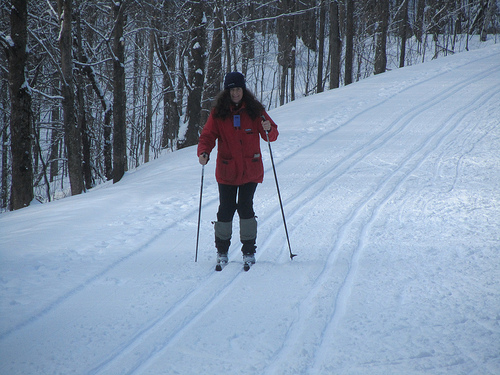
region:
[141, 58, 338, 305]
the woman is skiing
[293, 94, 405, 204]
ski tracks in the snow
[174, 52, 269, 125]
woman wearing a hat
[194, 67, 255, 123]
the hat is black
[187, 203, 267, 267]
the woman is wearing leg warmers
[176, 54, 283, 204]
the woman is wearing a red coat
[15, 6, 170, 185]
the trees have snow on them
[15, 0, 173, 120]
the trees have no leaves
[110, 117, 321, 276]
the woman is holding ski poles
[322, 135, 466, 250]
the sun is on the snow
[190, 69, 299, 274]
the woman standing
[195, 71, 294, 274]
the woman skiing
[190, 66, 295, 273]
the woman standing on skis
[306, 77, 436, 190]
the ski tracks on the snow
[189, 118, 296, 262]
the woman's ski poles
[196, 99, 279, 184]
the woman's red jacket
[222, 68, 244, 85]
the woman's beanie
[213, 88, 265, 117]
the woman's long hair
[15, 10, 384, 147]
the brown bare trees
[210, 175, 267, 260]
the woman's dark pants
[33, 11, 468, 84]
a row of trees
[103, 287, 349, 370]
a few sets of tracks in snow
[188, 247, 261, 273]
pair of white ski boots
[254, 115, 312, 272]
a black ski pole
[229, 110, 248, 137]
a small blue tag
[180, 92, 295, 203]
a bright red jacket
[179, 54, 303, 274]
an older woman skiing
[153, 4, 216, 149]
a snow covered tree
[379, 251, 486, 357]
a pile of snow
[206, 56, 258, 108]
a black knit cap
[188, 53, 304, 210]
Women is wearing a red jacket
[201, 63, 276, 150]
Women has a blue tag on jacket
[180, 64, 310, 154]
Women is wearing a beanie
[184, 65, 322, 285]
Women is holding ski poles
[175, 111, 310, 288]
Ski poles are black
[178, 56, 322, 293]
Skier in the snow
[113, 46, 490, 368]
Tracks in the snow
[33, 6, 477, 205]
Trees lining the trail edge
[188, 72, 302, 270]
Women is wearing black pants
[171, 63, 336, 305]
Women is wearing white boots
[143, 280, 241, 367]
the snow is white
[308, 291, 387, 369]
the snow is white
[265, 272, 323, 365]
the snow is white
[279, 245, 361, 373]
the snow is white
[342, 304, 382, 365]
the snow is white